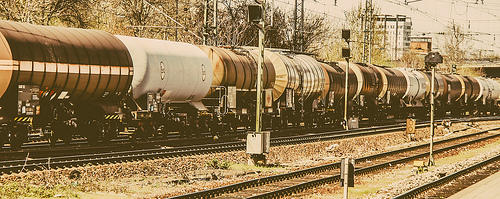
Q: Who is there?
A: No one.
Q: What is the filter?
A: Vintage.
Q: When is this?
A: Afternoon.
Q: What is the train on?
A: Tracks.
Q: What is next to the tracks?
A: Grass.